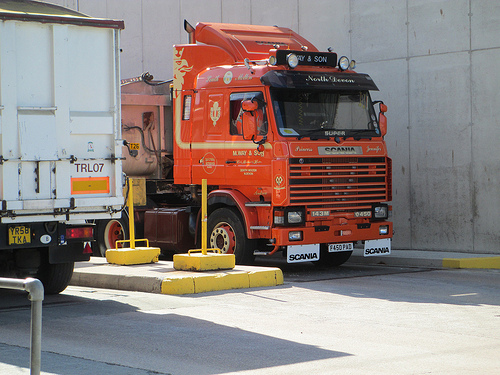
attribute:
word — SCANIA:
[323, 147, 354, 154]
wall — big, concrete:
[398, 18, 496, 247]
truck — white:
[4, 1, 126, 296]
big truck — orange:
[164, 6, 401, 281]